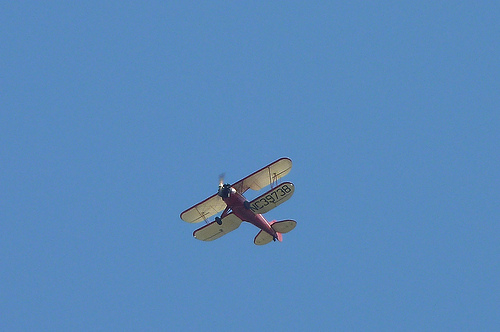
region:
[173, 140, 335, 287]
This is an aircraft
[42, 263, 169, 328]
Section of the sky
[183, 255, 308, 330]
Section of the sky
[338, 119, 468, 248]
Section of the sky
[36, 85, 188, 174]
Section of the sky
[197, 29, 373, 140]
Section of the sky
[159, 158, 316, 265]
Plane in the sky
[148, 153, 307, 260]
Plane flying in the air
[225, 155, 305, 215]
Wings on a plane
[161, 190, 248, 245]
Two wings on a plane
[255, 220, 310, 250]
Tail on a plane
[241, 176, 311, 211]
Number on a plane wing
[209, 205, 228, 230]
Wheel on a plane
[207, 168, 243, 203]
Propeller on a plane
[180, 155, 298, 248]
airplane flying in the sky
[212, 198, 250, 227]
two black landing wheels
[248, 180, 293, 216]
wing with black numbers and letters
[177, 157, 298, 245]
red and white airplane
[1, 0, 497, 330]
vast clear blue sky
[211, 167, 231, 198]
spinning propellor of an airplane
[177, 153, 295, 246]
small red airplane with white wings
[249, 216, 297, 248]
two small white wings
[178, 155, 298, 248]
small airplane flying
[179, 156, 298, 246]
airplane flying in air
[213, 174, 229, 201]
propeller engine on airplane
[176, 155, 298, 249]
red and creme airplane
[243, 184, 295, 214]
plane wing says NC39738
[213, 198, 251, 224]
black wheels on airplane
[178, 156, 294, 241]
plane has bi wing setup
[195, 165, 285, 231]
metal rods holding wings apart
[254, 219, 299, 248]
tail has three fins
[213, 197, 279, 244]
fixed landing gear on belly of plane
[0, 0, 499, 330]
sky is clear and blue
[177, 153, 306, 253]
a plane flying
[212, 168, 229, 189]
the propellers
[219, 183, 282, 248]
the body of plane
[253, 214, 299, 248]
the tail of plane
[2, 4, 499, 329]
the blue clear sky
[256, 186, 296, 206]
the numbers on the plane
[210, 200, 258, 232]
the wheels on the plane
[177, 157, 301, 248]
the wings of the plane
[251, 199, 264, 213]
the nc on plane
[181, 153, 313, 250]
a red and white plane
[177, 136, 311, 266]
the jet is flying